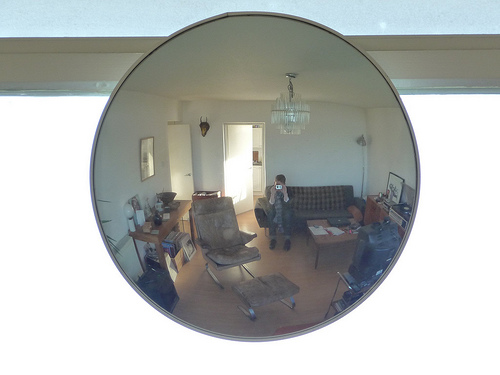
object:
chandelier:
[270, 73, 311, 135]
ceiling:
[199, 32, 290, 67]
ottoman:
[231, 271, 300, 321]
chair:
[191, 196, 262, 290]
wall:
[100, 144, 130, 187]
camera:
[275, 184, 283, 190]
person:
[268, 174, 292, 252]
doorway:
[224, 125, 263, 216]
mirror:
[88, 11, 420, 343]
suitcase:
[133, 266, 181, 315]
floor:
[193, 293, 225, 321]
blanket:
[295, 185, 344, 211]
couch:
[254, 184, 366, 235]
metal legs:
[237, 304, 257, 320]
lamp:
[356, 134, 367, 201]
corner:
[356, 105, 372, 116]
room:
[111, 101, 403, 336]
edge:
[220, 10, 290, 21]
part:
[134, 53, 150, 64]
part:
[312, 187, 321, 211]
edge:
[184, 124, 192, 129]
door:
[166, 121, 195, 200]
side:
[174, 136, 182, 153]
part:
[222, 229, 237, 240]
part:
[362, 157, 365, 168]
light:
[356, 134, 366, 147]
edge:
[254, 252, 263, 261]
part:
[224, 302, 235, 327]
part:
[149, 233, 163, 244]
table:
[128, 199, 199, 270]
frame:
[139, 136, 155, 183]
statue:
[199, 116, 211, 138]